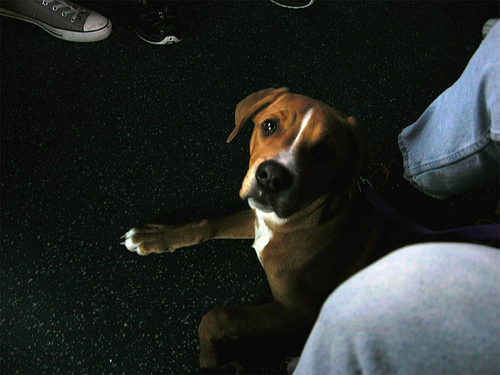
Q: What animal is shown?
A: Dog.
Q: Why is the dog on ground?
A: Scared.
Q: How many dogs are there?
A: One.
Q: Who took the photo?
A: Owner.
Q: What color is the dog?
A: Brown.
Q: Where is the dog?
A: In between feet.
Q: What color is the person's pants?
A: Blue.